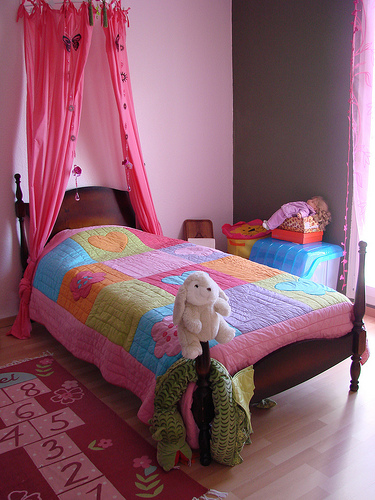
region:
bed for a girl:
[11, 174, 337, 392]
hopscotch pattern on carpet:
[6, 370, 130, 496]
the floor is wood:
[313, 434, 349, 465]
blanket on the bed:
[223, 260, 286, 328]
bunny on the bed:
[171, 271, 229, 361]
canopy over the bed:
[17, 5, 172, 255]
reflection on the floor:
[324, 412, 360, 495]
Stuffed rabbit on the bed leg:
[172, 269, 236, 359]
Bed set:
[15, 163, 365, 469]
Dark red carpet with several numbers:
[0, 355, 207, 498]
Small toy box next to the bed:
[249, 238, 342, 294]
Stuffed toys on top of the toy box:
[263, 193, 331, 233]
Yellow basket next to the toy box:
[221, 217, 269, 258]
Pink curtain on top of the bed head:
[8, 0, 182, 342]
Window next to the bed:
[336, 64, 369, 307]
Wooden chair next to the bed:
[182, 216, 215, 243]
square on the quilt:
[139, 322, 174, 362]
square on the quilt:
[94, 299, 129, 331]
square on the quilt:
[60, 293, 85, 304]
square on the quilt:
[306, 287, 334, 310]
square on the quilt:
[228, 255, 258, 282]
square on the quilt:
[87, 229, 140, 257]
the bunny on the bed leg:
[169, 270, 233, 363]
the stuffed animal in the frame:
[148, 352, 256, 477]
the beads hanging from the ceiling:
[48, 41, 84, 207]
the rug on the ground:
[0, 349, 163, 496]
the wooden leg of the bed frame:
[347, 238, 373, 397]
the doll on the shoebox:
[257, 188, 336, 248]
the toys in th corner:
[221, 194, 342, 257]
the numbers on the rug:
[1, 382, 118, 499]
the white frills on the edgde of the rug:
[193, 486, 231, 499]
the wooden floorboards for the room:
[265, 420, 373, 496]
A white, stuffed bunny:
[173, 271, 235, 357]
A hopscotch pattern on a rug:
[0, 371, 125, 499]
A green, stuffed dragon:
[149, 358, 254, 471]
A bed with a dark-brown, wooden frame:
[14, 172, 365, 465]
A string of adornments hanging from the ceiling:
[61, 1, 82, 200]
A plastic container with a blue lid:
[249, 239, 344, 292]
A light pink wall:
[0, 1, 233, 321]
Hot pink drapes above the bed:
[6, 0, 153, 336]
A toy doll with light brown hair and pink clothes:
[261, 197, 329, 231]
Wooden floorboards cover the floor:
[0, 313, 373, 497]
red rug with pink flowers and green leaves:
[0, 350, 214, 499]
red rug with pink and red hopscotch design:
[1, 349, 212, 499]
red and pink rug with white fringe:
[1, 349, 213, 499]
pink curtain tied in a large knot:
[8, 34, 95, 344]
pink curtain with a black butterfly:
[99, 34, 165, 240]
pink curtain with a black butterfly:
[8, 34, 95, 344]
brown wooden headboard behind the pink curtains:
[10, 171, 141, 278]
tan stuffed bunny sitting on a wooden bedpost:
[171, 269, 235, 360]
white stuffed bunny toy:
[167, 272, 237, 358]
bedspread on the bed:
[28, 221, 355, 403]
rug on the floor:
[6, 351, 214, 498]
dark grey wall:
[232, 1, 342, 241]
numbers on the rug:
[4, 377, 112, 499]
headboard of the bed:
[13, 167, 135, 251]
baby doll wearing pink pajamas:
[261, 190, 330, 232]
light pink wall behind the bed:
[3, 4, 234, 306]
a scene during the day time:
[37, 246, 293, 495]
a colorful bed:
[25, 233, 338, 455]